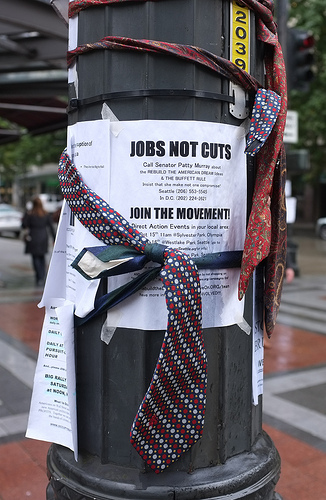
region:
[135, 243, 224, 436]
this is a neck tie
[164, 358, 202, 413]
the tie is red and black in color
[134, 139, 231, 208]
this is a notice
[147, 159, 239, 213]
the notice is in white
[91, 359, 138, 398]
the pole is metallic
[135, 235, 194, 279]
the tie is tied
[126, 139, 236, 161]
it s written job not cuts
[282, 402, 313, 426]
this is the pavement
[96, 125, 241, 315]
white paper on pole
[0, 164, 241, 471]
ties tied around pole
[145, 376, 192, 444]
dots on front of tie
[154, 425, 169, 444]
line of red dots on tie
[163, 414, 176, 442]
line of white dots on tie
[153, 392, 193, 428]
red and white dots on tie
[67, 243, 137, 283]
black and white end of tie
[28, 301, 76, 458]
white and black paper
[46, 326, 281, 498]
large black base of pole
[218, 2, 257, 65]
yellow sign on pole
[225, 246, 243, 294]
White plane being boarded.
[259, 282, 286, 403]
White plane being boarded.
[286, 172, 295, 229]
White plane being boarded.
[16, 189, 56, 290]
a woman walking on the road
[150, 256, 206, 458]
a multi color tie with the post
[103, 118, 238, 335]
white color advertisement notes pasted in the pole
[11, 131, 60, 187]
plants near the building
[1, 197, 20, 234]
white color car is parked in the side of the road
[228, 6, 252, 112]
numbers written on the pole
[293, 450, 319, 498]
floor tiles near the pole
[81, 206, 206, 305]
a tie knotted with black color cloth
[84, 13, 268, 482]
black color coated metal pole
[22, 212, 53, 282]
a woman wearing black color dress